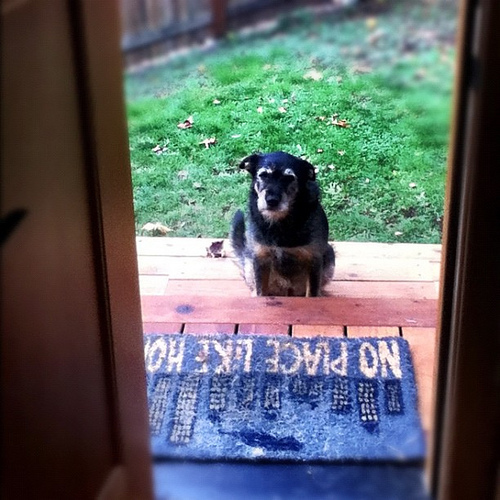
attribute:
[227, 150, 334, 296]
dog — black, brown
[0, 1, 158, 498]
door — brown, open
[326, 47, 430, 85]
leaves — brown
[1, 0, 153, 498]
wall — brown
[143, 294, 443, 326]
wooden plank — wooden 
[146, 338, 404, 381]
letters — white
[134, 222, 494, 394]
step — wooden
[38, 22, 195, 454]
door — open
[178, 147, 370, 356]
dog — black, brown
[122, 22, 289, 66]
fence — wooden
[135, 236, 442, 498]
floor — wooden, brown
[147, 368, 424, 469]
drawings — building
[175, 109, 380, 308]
dog — brown, black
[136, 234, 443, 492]
deck — wood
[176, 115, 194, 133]
leaf — brown